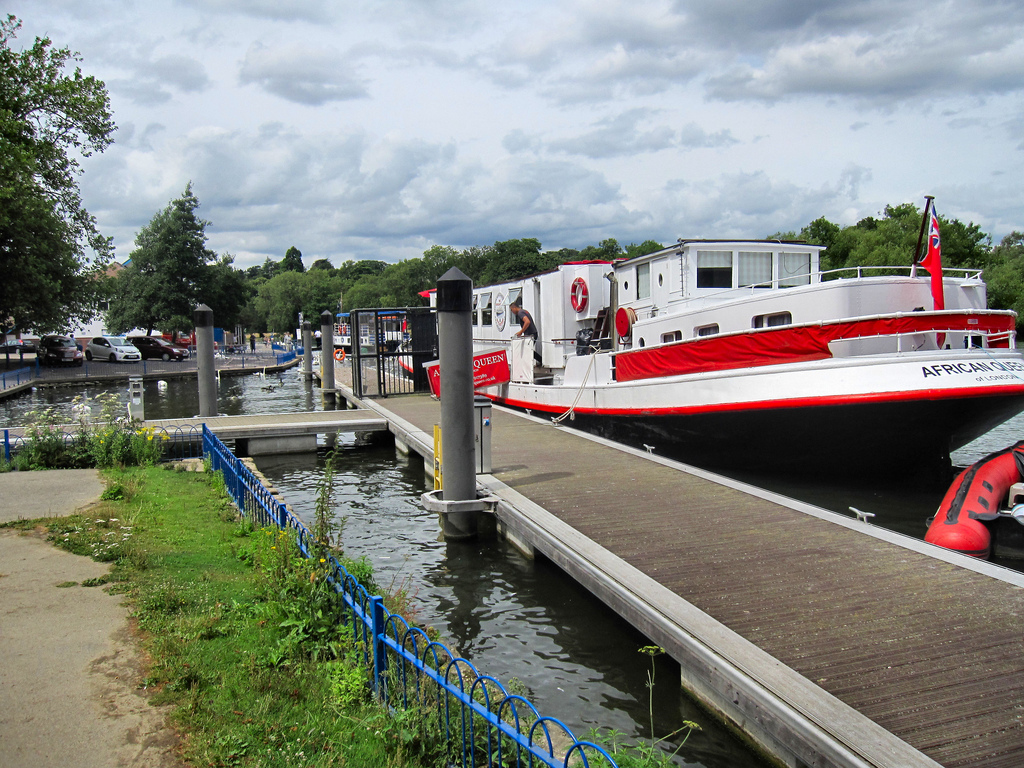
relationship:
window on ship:
[755, 310, 801, 324] [422, 204, 1015, 472]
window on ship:
[696, 322, 716, 336] [422, 204, 1015, 472]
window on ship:
[691, 323, 717, 341] [422, 204, 1015, 472]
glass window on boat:
[632, 331, 659, 345] [382, 208, 1022, 486]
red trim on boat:
[588, 374, 1005, 429] [463, 223, 1021, 407]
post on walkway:
[426, 253, 476, 571] [504, 391, 792, 625]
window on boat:
[694, 234, 854, 301] [497, 225, 1022, 413]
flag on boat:
[910, 178, 973, 306] [497, 225, 1022, 413]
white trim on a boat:
[577, 351, 1018, 412] [482, 201, 973, 443]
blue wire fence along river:
[359, 564, 485, 714] [381, 526, 541, 637]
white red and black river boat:
[787, 376, 816, 390] [448, 212, 987, 448]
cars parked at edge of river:
[65, 314, 191, 369] [426, 543, 565, 643]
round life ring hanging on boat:
[565, 279, 602, 314] [409, 219, 1015, 423]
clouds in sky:
[0, 29, 999, 267] [34, 1, 992, 261]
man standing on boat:
[498, 301, 557, 386] [425, 229, 1015, 437]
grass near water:
[95, 452, 441, 764] [231, 381, 707, 755]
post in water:
[425, 253, 479, 571] [202, 398, 669, 761]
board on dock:
[408, 357, 1008, 753] [386, 374, 1005, 737]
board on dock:
[408, 357, 1009, 753] [570, 437, 614, 481]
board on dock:
[408, 357, 1008, 753] [615, 459, 721, 546]